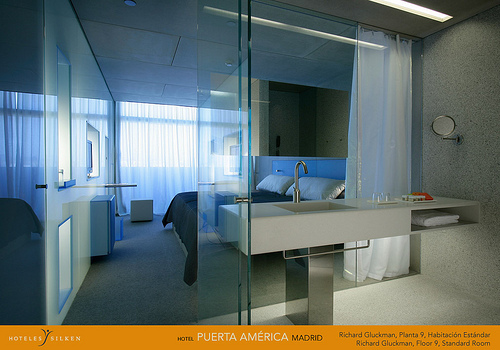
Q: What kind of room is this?
A: A hotel room.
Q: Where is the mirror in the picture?
A: The wall on the right side of the bathroom.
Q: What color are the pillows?
A: White.